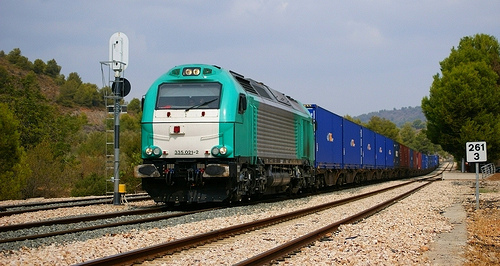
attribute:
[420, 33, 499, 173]
tree — tall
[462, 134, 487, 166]
sign — white, square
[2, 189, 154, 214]
track — steel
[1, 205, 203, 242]
track — steel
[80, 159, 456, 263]
track — steel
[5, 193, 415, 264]
track — empty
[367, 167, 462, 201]
track — empty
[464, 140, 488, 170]
sign — small, white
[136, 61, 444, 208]
train — green, traveling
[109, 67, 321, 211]
engine — green, white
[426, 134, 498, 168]
sign — white, black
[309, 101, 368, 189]
train car — blue 